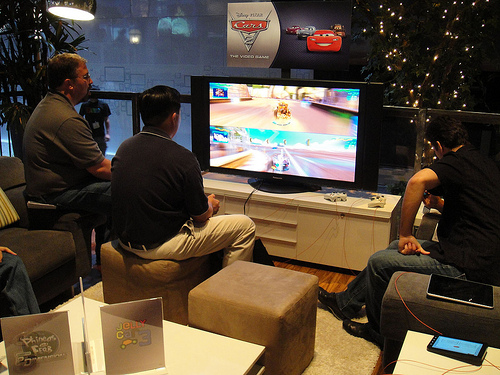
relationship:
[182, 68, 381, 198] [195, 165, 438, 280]
television on stand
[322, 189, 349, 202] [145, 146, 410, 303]
controller are on stand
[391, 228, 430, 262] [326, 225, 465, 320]
hand on thigh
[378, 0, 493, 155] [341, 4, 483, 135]
lights on tree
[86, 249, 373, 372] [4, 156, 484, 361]
rug on floor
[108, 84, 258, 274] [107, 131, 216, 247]
guy wearing shirt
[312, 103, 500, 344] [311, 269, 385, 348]
guy wearing shoe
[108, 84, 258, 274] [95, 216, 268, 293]
guy wearing pants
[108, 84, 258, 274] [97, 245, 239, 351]
guy sitting on bench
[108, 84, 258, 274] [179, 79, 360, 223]
guy playing video games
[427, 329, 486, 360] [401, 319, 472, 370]
computer on counter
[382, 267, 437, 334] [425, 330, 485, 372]
cable connected to tablet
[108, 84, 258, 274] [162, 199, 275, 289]
guy wearing khakis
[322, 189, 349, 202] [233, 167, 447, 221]
controller on table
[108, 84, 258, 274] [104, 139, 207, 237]
guy wearing shirt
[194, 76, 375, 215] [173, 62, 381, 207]
game scene on tv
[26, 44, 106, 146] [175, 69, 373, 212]
guy watching tv screen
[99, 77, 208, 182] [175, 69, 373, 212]
guy watching tv screen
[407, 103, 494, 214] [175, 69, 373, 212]
guy watching tv screen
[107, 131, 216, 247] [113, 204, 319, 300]
shirt and pants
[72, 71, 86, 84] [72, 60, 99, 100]
glass on man's face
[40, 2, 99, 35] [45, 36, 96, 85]
light above man's head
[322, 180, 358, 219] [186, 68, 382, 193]
controller by tv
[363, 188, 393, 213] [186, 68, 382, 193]
controller by tv